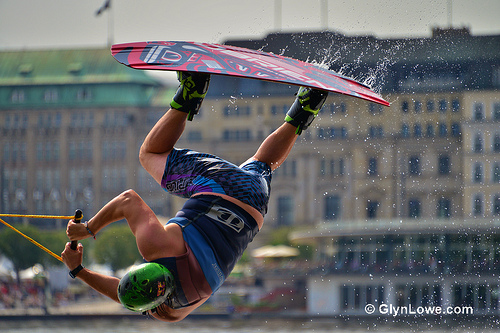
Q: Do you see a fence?
A: No, there are no fences.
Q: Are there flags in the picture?
A: Yes, there is a flag.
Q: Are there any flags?
A: Yes, there is a flag.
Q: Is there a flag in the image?
A: Yes, there is a flag.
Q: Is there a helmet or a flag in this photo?
A: Yes, there is a flag.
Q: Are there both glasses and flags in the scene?
A: No, there is a flag but no glasses.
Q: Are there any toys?
A: No, there are no toys.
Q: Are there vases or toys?
A: No, there are no toys or vases.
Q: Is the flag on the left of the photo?
A: Yes, the flag is on the left of the image.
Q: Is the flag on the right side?
A: No, the flag is on the left of the image.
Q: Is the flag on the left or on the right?
A: The flag is on the left of the image.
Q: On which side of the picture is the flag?
A: The flag is on the left of the image.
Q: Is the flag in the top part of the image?
A: Yes, the flag is in the top of the image.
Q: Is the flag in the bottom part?
A: No, the flag is in the top of the image.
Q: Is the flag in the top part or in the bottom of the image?
A: The flag is in the top of the image.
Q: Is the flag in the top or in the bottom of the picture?
A: The flag is in the top of the image.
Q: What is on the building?
A: The flag is on the building.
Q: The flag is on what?
A: The flag is on the building.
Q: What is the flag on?
A: The flag is on the building.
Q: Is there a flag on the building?
A: Yes, there is a flag on the building.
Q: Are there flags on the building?
A: Yes, there is a flag on the building.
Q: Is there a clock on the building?
A: No, there is a flag on the building.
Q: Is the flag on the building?
A: Yes, the flag is on the building.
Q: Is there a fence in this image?
A: No, there are no fences.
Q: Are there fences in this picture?
A: No, there are no fences.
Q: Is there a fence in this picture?
A: No, there are no fences.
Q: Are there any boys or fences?
A: No, there are no fences or boys.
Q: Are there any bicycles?
A: No, there are no bicycles.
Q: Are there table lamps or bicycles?
A: No, there are no bicycles or table lamps.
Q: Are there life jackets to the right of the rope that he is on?
A: Yes, there is a life jacket to the right of the rope.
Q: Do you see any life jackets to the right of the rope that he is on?
A: Yes, there is a life jacket to the right of the rope.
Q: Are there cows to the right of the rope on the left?
A: No, there is a life jacket to the right of the rope.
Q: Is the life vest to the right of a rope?
A: Yes, the life vest is to the right of a rope.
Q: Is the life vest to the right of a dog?
A: No, the life vest is to the right of a rope.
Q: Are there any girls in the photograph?
A: No, there are no girls.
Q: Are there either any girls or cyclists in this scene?
A: No, there are no girls or cyclists.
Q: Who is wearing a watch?
A: The man is wearing a watch.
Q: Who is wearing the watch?
A: The man is wearing a watch.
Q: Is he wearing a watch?
A: Yes, the man is wearing a watch.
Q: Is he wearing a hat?
A: No, the man is wearing a watch.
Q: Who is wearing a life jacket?
A: The man is wearing a life jacket.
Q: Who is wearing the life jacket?
A: The man is wearing a life jacket.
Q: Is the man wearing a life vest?
A: Yes, the man is wearing a life vest.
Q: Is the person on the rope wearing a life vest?
A: Yes, the man is wearing a life vest.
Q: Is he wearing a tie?
A: No, the man is wearing a life vest.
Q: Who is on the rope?
A: The man is on the rope.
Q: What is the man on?
A: The man is on the rope.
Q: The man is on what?
A: The man is on the rope.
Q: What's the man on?
A: The man is on the rope.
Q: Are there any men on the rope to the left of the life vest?
A: Yes, there is a man on the rope.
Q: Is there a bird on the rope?
A: No, there is a man on the rope.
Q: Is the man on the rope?
A: Yes, the man is on the rope.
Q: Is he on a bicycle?
A: No, the man is on the rope.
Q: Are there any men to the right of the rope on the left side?
A: Yes, there is a man to the right of the rope.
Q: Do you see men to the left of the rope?
A: No, the man is to the right of the rope.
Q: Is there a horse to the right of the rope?
A: No, there is a man to the right of the rope.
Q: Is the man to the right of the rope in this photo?
A: Yes, the man is to the right of the rope.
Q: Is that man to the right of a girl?
A: No, the man is to the right of the rope.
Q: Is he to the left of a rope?
A: No, the man is to the right of a rope.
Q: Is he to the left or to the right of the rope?
A: The man is to the right of the rope.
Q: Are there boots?
A: Yes, there are boots.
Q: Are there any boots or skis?
A: Yes, there are boots.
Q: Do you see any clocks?
A: No, there are no clocks.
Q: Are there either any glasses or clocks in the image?
A: No, there are no clocks or glasses.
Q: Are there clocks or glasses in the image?
A: No, there are no clocks or glasses.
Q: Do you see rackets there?
A: No, there are no rackets.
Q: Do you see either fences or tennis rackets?
A: No, there are no tennis rackets or fences.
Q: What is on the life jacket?
A: The logo is on the life jacket.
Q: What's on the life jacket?
A: The logo is on the life jacket.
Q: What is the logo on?
A: The logo is on the life jacket.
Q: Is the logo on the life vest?
A: Yes, the logo is on the life vest.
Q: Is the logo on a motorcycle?
A: No, the logo is on the life vest.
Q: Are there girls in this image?
A: No, there are no girls.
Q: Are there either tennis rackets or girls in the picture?
A: No, there are no girls or tennis rackets.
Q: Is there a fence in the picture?
A: No, there are no fences.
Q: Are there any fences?
A: No, there are no fences.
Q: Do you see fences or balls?
A: No, there are no fences or balls.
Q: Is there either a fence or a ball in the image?
A: No, there are no fences or balls.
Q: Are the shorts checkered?
A: Yes, the shorts are checkered.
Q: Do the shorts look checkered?
A: Yes, the shorts are checkered.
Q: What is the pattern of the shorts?
A: The shorts are checkered.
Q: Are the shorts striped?
A: No, the shorts are checkered.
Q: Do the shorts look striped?
A: No, the shorts are checkered.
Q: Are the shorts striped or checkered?
A: The shorts are checkered.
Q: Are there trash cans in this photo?
A: No, there are no trash cans.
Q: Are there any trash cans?
A: No, there are no trash cans.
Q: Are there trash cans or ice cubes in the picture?
A: No, there are no trash cans or ice cubes.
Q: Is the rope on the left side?
A: Yes, the rope is on the left of the image.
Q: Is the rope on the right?
A: No, the rope is on the left of the image.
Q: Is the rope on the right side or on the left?
A: The rope is on the left of the image.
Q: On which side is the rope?
A: The rope is on the left of the image.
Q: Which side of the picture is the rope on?
A: The rope is on the left of the image.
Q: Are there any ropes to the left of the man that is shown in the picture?
A: Yes, there is a rope to the left of the man.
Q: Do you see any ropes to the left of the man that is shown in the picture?
A: Yes, there is a rope to the left of the man.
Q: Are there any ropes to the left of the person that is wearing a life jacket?
A: Yes, there is a rope to the left of the man.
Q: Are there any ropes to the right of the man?
A: No, the rope is to the left of the man.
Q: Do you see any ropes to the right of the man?
A: No, the rope is to the left of the man.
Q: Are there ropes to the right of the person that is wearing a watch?
A: No, the rope is to the left of the man.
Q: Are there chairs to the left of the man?
A: No, there is a rope to the left of the man.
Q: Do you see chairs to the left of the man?
A: No, there is a rope to the left of the man.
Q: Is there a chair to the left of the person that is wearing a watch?
A: No, there is a rope to the left of the man.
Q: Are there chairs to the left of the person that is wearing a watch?
A: No, there is a rope to the left of the man.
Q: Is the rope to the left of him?
A: Yes, the rope is to the left of the man.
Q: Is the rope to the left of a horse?
A: No, the rope is to the left of the man.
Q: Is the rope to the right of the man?
A: No, the rope is to the left of the man.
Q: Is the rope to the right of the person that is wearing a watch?
A: No, the rope is to the left of the man.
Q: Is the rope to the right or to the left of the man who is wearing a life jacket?
A: The rope is to the left of the man.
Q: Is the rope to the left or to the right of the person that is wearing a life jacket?
A: The rope is to the left of the man.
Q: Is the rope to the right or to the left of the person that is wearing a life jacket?
A: The rope is to the left of the man.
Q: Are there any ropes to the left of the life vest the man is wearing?
A: Yes, there is a rope to the left of the life jacket.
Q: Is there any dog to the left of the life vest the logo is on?
A: No, there is a rope to the left of the life vest.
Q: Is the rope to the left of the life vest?
A: Yes, the rope is to the left of the life vest.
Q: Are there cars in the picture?
A: No, there are no cars.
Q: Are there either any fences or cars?
A: No, there are no cars or fences.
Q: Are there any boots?
A: Yes, there are boots.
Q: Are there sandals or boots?
A: Yes, there are boots.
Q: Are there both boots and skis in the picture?
A: No, there are boots but no skis.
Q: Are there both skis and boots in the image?
A: No, there are boots but no skis.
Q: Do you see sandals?
A: No, there are no sandals.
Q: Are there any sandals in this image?
A: No, there are no sandals.